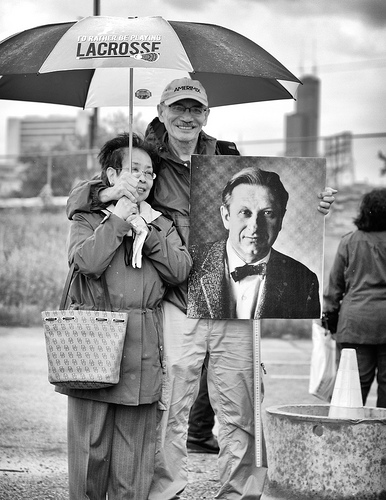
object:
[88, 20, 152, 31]
umbrella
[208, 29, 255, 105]
umbrella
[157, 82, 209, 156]
man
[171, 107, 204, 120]
sunglasess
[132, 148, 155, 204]
woman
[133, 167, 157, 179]
glasses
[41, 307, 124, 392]
purse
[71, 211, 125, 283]
arm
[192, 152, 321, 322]
portrait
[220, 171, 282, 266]
man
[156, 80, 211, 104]
cap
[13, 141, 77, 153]
tree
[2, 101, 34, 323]
side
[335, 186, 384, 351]
person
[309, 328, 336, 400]
bag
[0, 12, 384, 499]
image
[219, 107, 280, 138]
image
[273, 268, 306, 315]
image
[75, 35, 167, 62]
logo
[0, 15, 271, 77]
umbrella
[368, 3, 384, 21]
clouds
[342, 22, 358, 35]
clouds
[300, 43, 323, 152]
building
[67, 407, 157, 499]
pants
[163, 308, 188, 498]
pants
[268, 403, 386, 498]
container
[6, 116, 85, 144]
building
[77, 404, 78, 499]
pinstripe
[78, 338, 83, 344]
bourke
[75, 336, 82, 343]
dooney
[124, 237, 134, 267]
gloves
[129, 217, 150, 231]
hand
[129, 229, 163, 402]
jacket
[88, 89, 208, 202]
couple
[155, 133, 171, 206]
jacket